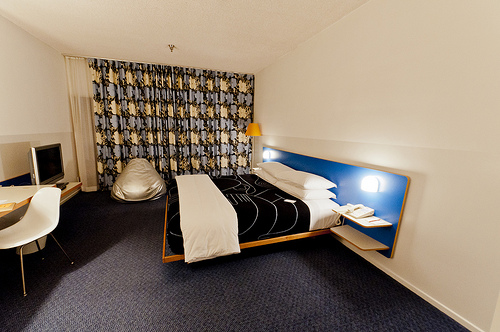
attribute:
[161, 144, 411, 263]
bed — made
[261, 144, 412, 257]
headboard — blue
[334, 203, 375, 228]
phone — white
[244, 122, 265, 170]
lamp — orange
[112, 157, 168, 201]
bean bag — silver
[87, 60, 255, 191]
curtain — dark colored, blue, yellow, colorful, drawn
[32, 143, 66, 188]
television — small, off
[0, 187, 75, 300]
chair — white, rounded, empty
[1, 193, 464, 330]
carpet — dark colored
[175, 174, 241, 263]
blanket — white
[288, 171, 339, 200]
pillows — white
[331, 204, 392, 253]
shelves — mounted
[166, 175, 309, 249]
comforter — black, white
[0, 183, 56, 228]
desk — white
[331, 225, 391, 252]
shelf — empty